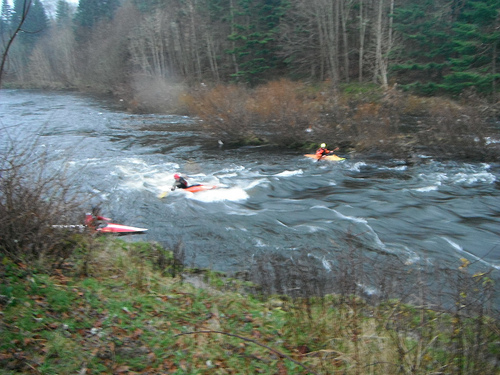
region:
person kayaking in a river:
[293, 128, 387, 176]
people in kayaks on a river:
[28, 106, 478, 284]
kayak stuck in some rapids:
[143, 148, 253, 213]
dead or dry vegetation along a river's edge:
[97, 56, 282, 154]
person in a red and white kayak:
[56, 195, 175, 254]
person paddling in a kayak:
[285, 123, 383, 187]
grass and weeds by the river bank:
[45, 247, 467, 373]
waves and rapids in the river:
[261, 174, 451, 246]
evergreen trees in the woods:
[389, 11, 498, 108]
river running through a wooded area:
[2, 1, 229, 154]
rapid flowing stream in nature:
[6, 21, 491, 341]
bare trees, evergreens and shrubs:
[120, 0, 490, 81]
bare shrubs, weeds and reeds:
[16, 215, 471, 370]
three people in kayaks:
[15, 121, 382, 266]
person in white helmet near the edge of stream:
[300, 125, 360, 170]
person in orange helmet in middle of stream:
[145, 155, 250, 220]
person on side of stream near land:
[35, 190, 155, 255]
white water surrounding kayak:
[125, 130, 245, 215]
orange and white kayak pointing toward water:
[40, 200, 165, 250]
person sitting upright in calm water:
[291, 125, 368, 180]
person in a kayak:
[305, 142, 345, 164]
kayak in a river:
[0, 84, 499, 316]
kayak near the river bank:
[47, 207, 147, 239]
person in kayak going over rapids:
[157, 172, 217, 198]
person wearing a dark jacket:
[172, 171, 189, 187]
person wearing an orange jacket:
[314, 143, 335, 161]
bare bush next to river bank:
[0, 115, 107, 275]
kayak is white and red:
[57, 220, 149, 240]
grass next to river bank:
[26, 240, 281, 374]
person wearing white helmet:
[319, 142, 326, 147]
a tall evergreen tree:
[386, 3, 498, 110]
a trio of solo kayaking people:
[40, 141, 342, 257]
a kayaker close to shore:
[44, 200, 156, 244]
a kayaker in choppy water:
[109, 142, 269, 214]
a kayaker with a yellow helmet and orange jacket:
[302, 138, 347, 168]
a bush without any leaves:
[0, 109, 117, 289]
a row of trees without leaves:
[12, 0, 234, 114]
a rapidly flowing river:
[0, 81, 497, 317]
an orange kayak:
[42, 219, 151, 236]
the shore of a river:
[29, 209, 496, 344]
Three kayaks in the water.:
[50, 132, 372, 248]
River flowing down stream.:
[0, 72, 490, 324]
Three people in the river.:
[39, 129, 341, 251]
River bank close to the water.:
[1, 221, 493, 371]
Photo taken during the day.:
[4, 15, 490, 368]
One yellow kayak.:
[290, 144, 348, 168]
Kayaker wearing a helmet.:
[167, 171, 213, 191]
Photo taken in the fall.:
[7, 0, 494, 168]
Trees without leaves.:
[16, 16, 247, 113]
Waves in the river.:
[65, 123, 494, 324]